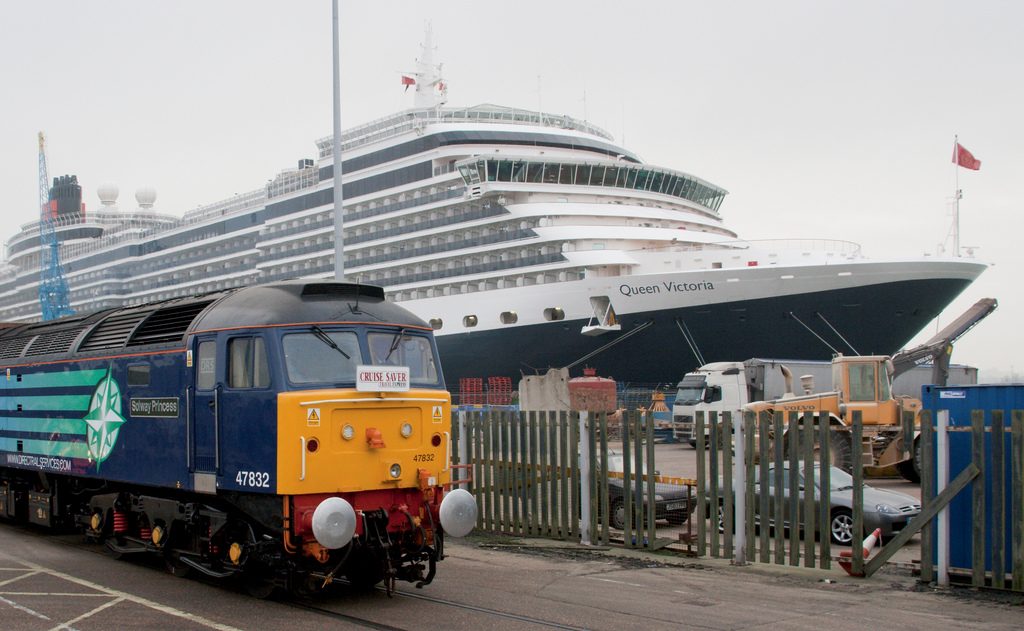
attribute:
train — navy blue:
[4, 250, 477, 621]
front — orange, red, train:
[256, 310, 519, 617]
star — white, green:
[65, 359, 136, 490]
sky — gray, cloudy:
[1, 5, 1008, 382]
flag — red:
[931, 122, 985, 200]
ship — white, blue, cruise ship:
[17, 39, 998, 394]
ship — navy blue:
[434, 274, 976, 429]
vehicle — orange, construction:
[719, 327, 935, 520]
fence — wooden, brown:
[465, 380, 1009, 619]